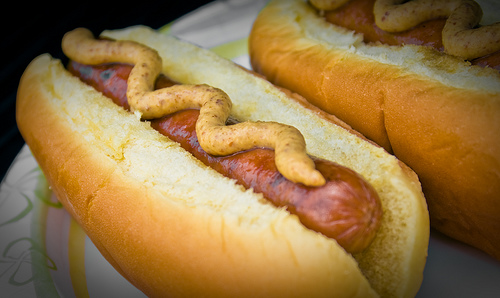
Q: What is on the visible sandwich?
A: Hotdog and mustard.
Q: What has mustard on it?
A: A visible sandwich.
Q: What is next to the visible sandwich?
A: Another visible sandwich.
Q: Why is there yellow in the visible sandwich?
A: It's mustard.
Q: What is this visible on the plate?
A: A sandwich.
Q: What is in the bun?
A: Hot dog.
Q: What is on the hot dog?
A: Mustard.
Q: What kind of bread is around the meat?
A: Hot dog bun.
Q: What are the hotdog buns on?
A: Paper plate.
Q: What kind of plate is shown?
A: Paper.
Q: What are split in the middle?
A: Buns.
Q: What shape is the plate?
A: Circular.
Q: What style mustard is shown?
A: Deli.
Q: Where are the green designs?
A: On the plate.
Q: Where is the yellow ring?
A: On the plate.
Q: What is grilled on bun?
A: The hotdog.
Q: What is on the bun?
A: Hot Dog.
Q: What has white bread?
A: A hot dog bun.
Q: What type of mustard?
A: Yellow mustard.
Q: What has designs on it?
A: White paper plate.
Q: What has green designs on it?
A: A paper plate.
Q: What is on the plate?
A: A cooked hot dog.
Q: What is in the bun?
A: A hot dog.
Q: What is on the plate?
A: A hotdog.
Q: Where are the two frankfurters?
A: On a paper plate.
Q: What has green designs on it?
A: The white paper.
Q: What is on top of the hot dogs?
A: Mustard.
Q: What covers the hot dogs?
A: Buns.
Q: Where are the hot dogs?
A: On a paper plate.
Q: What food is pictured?
A: Hot dogs.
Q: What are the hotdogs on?
A: A plate.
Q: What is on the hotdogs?
A: Mustard.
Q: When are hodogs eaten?
A: When people are hungry.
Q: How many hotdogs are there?
A: 2.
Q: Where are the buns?
A: On the plate.